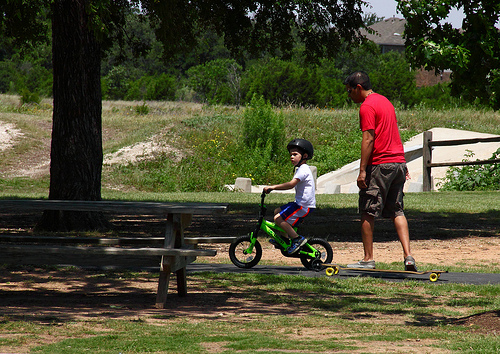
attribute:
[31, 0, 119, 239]
tree trunk — large 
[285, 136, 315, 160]
helmet — black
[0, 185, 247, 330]
picnic table — brown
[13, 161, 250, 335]
table — wooden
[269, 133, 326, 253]
boy — young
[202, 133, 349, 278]
bike — green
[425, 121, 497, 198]
fence — wooden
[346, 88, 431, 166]
shirt — red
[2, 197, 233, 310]
bench — wooden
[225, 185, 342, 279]
bike — green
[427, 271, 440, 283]
wheels — yellow 